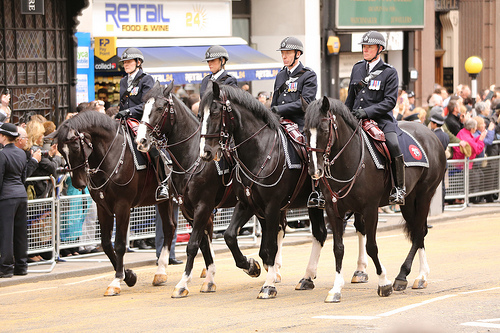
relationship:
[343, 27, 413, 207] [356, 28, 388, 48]
rider wearing helmet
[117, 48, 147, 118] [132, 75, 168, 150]
police on horse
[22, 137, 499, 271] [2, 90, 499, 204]
fence in front of crowd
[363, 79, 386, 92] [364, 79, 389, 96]
patch on blazer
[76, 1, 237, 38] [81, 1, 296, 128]
sign over business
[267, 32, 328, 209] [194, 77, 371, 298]
person on horse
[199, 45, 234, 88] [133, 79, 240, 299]
person on horse